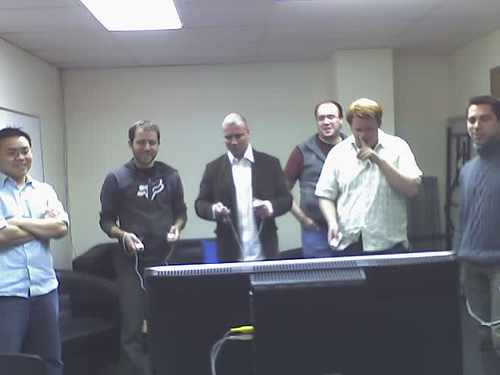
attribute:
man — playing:
[315, 97, 423, 259]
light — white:
[78, 2, 187, 36]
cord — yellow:
[183, 300, 280, 360]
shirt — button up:
[314, 128, 424, 251]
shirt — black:
[94, 156, 190, 252]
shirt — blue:
[0, 170, 71, 297]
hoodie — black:
[98, 159, 188, 257]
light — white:
[278, 96, 324, 114]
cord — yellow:
[214, 320, 252, 336]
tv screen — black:
[142, 239, 472, 373]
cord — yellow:
[229, 321, 254, 334]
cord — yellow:
[223, 324, 257, 343]